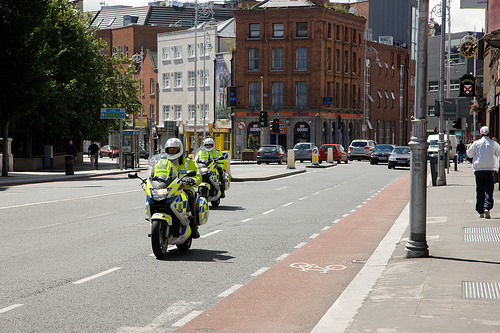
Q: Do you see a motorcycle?
A: Yes, there are motorcycles.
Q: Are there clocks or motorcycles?
A: Yes, there are motorcycles.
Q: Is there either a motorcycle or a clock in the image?
A: Yes, there are motorcycles.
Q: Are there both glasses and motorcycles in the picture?
A: No, there are motorcycles but no glasses.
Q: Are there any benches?
A: No, there are no benches.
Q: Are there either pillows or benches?
A: No, there are no benches or pillows.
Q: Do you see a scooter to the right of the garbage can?
A: No, there are motorcycles to the right of the garbage can.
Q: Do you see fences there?
A: No, there are no fences.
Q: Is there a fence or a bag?
A: No, there are no fences or bags.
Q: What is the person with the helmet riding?
A: The person is riding a motorcycle.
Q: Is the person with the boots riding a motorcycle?
A: Yes, the person is riding a motorcycle.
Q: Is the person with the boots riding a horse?
A: No, the person is riding a motorcycle.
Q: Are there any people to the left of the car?
A: Yes, there is a person to the left of the car.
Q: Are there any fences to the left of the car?
A: No, there is a person to the left of the car.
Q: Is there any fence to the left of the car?
A: No, there is a person to the left of the car.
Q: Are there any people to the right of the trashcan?
A: Yes, there is a person to the right of the trashcan.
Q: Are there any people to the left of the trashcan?
A: No, the person is to the right of the trashcan.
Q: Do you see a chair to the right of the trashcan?
A: No, there is a person to the right of the trashcan.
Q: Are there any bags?
A: No, there are no bags.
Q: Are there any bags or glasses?
A: No, there are no bags or glasses.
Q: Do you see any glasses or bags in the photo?
A: No, there are no bags or glasses.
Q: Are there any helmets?
A: Yes, there is a helmet.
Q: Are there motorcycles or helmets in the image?
A: Yes, there is a helmet.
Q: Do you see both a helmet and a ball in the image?
A: No, there is a helmet but no balls.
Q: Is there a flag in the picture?
A: No, there are no flags.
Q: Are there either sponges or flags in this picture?
A: No, there are no flags or sponges.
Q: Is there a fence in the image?
A: No, there are no fences.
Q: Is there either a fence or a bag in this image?
A: No, there are no fences or bags.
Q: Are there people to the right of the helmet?
A: Yes, there is a person to the right of the helmet.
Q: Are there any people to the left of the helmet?
A: No, the person is to the right of the helmet.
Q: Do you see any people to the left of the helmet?
A: No, the person is to the right of the helmet.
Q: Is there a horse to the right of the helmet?
A: No, there is a person to the right of the helmet.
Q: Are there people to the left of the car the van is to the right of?
A: Yes, there is a person to the left of the car.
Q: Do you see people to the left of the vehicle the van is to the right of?
A: Yes, there is a person to the left of the car.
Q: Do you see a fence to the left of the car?
A: No, there is a person to the left of the car.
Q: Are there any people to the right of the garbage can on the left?
A: Yes, there is a person to the right of the garbage bin.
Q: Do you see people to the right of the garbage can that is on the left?
A: Yes, there is a person to the right of the garbage bin.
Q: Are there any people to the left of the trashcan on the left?
A: No, the person is to the right of the garbage can.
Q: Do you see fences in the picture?
A: No, there are no fences.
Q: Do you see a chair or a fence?
A: No, there are no fences or chairs.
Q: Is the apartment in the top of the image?
A: Yes, the apartment is in the top of the image.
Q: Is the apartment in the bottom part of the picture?
A: No, the apartment is in the top of the image.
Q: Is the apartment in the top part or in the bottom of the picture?
A: The apartment is in the top of the image.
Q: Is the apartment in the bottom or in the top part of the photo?
A: The apartment is in the top of the image.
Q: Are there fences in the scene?
A: No, there are no fences.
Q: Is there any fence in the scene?
A: No, there are no fences.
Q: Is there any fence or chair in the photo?
A: No, there are no fences or chairs.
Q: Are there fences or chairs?
A: No, there are no fences or chairs.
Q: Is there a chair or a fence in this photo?
A: No, there are no fences or chairs.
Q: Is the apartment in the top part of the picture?
A: Yes, the apartment is in the top of the image.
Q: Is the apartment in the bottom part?
A: No, the apartment is in the top of the image.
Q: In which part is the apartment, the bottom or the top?
A: The apartment is in the top of the image.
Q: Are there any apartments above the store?
A: Yes, there is an apartment above the store.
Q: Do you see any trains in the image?
A: No, there are no trains.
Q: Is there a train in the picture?
A: No, there are no trains.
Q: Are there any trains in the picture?
A: No, there are no trains.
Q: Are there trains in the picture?
A: No, there are no trains.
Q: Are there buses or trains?
A: No, there are no trains or buses.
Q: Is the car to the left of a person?
A: Yes, the car is to the left of a person.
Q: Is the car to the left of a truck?
A: No, the car is to the left of a person.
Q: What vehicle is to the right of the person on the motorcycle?
A: The vehicle is a car.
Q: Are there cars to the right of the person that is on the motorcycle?
A: Yes, there is a car to the right of the person.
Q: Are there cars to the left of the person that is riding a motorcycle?
A: No, the car is to the right of the person.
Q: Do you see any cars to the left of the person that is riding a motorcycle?
A: No, the car is to the right of the person.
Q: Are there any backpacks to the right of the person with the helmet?
A: No, there is a car to the right of the person.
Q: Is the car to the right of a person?
A: Yes, the car is to the right of a person.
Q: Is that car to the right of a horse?
A: No, the car is to the right of a person.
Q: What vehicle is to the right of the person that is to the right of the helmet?
A: The vehicle is a car.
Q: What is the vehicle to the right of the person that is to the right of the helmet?
A: The vehicle is a car.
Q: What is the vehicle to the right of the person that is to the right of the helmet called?
A: The vehicle is a car.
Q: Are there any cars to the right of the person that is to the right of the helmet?
A: Yes, there is a car to the right of the person.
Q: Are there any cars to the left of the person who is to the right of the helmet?
A: No, the car is to the right of the person.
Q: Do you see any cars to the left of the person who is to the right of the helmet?
A: No, the car is to the right of the person.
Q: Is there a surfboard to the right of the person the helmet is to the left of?
A: No, there is a car to the right of the person.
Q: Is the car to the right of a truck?
A: No, the car is to the right of the person.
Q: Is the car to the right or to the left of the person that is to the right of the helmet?
A: The car is to the right of the person.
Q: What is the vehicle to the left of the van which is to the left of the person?
A: The vehicle is a car.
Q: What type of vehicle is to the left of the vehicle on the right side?
A: The vehicle is a car.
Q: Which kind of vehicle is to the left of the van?
A: The vehicle is a car.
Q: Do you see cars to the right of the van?
A: No, the car is to the left of the van.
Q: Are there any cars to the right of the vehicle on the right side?
A: No, the car is to the left of the van.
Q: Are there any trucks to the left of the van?
A: No, there is a car to the left of the van.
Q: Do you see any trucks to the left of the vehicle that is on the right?
A: No, there is a car to the left of the van.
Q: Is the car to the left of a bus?
A: No, the car is to the left of the van.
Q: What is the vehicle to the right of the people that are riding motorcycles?
A: The vehicle is a car.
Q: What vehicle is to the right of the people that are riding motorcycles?
A: The vehicle is a car.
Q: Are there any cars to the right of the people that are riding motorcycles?
A: Yes, there is a car to the right of the people.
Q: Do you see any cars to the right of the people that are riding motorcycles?
A: Yes, there is a car to the right of the people.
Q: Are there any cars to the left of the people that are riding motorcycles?
A: No, the car is to the right of the people.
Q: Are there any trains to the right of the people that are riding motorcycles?
A: No, there is a car to the right of the people.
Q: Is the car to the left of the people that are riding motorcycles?
A: No, the car is to the right of the people.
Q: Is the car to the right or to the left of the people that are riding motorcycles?
A: The car is to the right of the people.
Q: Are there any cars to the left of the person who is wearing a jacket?
A: Yes, there is a car to the left of the person.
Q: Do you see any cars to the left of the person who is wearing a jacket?
A: Yes, there is a car to the left of the person.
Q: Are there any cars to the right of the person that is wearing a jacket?
A: No, the car is to the left of the person.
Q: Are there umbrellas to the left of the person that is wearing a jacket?
A: No, there is a car to the left of the person.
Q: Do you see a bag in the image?
A: No, there are no bags.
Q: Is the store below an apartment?
A: Yes, the store is below an apartment.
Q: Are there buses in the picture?
A: No, there are no buses.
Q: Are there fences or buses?
A: No, there are no buses or fences.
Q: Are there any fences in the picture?
A: No, there are no fences.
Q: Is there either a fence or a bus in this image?
A: No, there are no fences or buses.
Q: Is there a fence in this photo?
A: No, there are no fences.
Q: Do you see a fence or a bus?
A: No, there are no fences or buses.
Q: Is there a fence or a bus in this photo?
A: No, there are no fences or buses.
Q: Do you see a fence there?
A: No, there are no fences.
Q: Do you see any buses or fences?
A: No, there are no fences or buses.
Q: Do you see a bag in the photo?
A: No, there are no bags.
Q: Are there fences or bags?
A: No, there are no bags or fences.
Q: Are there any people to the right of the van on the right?
A: Yes, there is a person to the right of the van.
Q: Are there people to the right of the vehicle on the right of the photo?
A: Yes, there is a person to the right of the van.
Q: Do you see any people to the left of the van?
A: No, the person is to the right of the van.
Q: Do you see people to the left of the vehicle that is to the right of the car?
A: No, the person is to the right of the van.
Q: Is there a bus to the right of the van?
A: No, there is a person to the right of the van.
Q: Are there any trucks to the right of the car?
A: No, there is a person to the right of the car.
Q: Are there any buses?
A: No, there are no buses.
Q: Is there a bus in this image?
A: No, there are no buses.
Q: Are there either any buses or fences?
A: No, there are no buses or fences.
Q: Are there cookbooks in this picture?
A: No, there are no cookbooks.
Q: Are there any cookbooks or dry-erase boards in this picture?
A: No, there are no cookbooks or dry-erase boards.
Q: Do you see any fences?
A: No, there are no fences.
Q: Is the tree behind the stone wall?
A: Yes, the tree is behind the wall.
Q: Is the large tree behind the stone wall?
A: Yes, the tree is behind the wall.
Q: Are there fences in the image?
A: No, there are no fences.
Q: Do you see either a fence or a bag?
A: No, there are no fences or bags.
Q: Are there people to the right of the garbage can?
A: Yes, there are people to the right of the garbage can.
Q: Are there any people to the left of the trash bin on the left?
A: No, the people are to the right of the garbage bin.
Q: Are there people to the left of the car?
A: Yes, there are people to the left of the car.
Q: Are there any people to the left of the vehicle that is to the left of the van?
A: Yes, there are people to the left of the car.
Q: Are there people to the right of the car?
A: No, the people are to the left of the car.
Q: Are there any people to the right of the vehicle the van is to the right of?
A: No, the people are to the left of the car.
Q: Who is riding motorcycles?
A: The people are riding motorcycles.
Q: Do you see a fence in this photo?
A: No, there are no fences.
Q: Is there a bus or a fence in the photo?
A: No, there are no fences or buses.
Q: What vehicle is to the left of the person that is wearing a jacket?
A: The vehicle is a van.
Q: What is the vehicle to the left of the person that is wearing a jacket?
A: The vehicle is a van.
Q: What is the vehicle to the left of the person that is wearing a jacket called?
A: The vehicle is a van.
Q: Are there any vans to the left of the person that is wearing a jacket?
A: Yes, there is a van to the left of the person.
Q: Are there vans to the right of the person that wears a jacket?
A: No, the van is to the left of the person.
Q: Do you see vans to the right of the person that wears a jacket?
A: No, the van is to the left of the person.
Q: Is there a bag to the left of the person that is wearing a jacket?
A: No, there is a van to the left of the person.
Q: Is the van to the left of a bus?
A: No, the van is to the left of the person.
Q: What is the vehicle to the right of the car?
A: The vehicle is a van.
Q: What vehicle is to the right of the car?
A: The vehicle is a van.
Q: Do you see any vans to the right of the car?
A: Yes, there is a van to the right of the car.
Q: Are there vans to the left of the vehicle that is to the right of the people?
A: No, the van is to the right of the car.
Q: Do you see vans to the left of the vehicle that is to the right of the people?
A: No, the van is to the right of the car.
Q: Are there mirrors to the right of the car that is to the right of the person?
A: No, there is a van to the right of the car.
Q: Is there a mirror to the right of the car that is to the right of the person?
A: No, there is a van to the right of the car.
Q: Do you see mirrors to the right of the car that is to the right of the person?
A: No, there is a van to the right of the car.